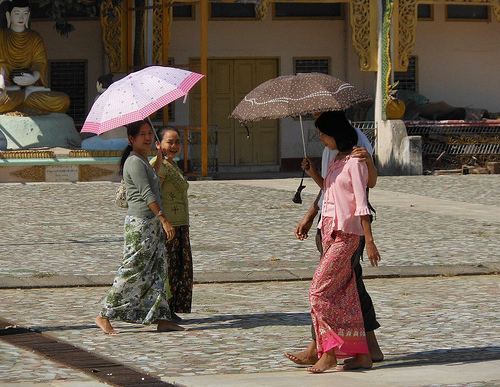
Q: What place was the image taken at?
A: It was taken at the street.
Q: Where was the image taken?
A: It was taken at the street.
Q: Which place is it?
A: It is a street.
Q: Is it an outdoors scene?
A: Yes, it is outdoors.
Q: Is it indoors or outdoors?
A: It is outdoors.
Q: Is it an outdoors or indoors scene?
A: It is outdoors.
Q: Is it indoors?
A: No, it is outdoors.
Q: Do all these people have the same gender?
A: No, they are both male and female.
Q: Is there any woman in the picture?
A: Yes, there is a woman.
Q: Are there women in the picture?
A: Yes, there is a woman.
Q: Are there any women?
A: Yes, there is a woman.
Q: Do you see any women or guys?
A: Yes, there is a woman.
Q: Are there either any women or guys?
A: Yes, there is a woman.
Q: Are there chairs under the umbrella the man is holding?
A: No, there is a woman under the umbrella.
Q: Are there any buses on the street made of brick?
A: No, there is a woman on the street.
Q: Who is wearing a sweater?
A: The woman is wearing a sweater.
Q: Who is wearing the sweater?
A: The woman is wearing a sweater.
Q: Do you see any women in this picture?
A: Yes, there is a woman.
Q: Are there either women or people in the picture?
A: Yes, there is a woman.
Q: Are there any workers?
A: No, there are no workers.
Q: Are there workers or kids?
A: No, there are no workers or kids.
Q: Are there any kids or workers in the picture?
A: No, there are no workers or kids.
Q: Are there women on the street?
A: Yes, there is a woman on the street.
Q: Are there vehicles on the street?
A: No, there is a woman on the street.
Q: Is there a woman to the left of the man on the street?
A: Yes, there is a woman to the left of the man.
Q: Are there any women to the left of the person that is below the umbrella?
A: Yes, there is a woman to the left of the man.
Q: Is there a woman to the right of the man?
A: No, the woman is to the left of the man.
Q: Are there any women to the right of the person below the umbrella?
A: No, the woman is to the left of the man.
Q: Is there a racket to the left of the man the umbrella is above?
A: No, there is a woman to the left of the man.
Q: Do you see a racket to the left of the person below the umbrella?
A: No, there is a woman to the left of the man.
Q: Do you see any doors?
A: Yes, there is a door.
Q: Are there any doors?
A: Yes, there is a door.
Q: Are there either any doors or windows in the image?
A: Yes, there is a door.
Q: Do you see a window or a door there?
A: Yes, there is a door.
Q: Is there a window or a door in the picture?
A: Yes, there is a door.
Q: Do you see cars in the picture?
A: No, there are no cars.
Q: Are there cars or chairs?
A: No, there are no cars or chairs.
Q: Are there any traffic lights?
A: No, there are no traffic lights.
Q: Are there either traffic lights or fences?
A: No, there are no traffic lights or fences.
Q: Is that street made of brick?
A: Yes, the street is made of brick.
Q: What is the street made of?
A: The street is made of brick.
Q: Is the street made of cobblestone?
A: No, the street is made of brick.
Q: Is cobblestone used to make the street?
A: No, the street is made of brick.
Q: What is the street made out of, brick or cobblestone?
A: The street is made of brick.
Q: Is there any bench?
A: No, there are no benches.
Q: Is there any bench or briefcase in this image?
A: No, there are no benches or briefcases.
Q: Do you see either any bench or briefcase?
A: No, there are no benches or briefcases.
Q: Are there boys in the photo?
A: No, there are no boys.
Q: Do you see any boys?
A: No, there are no boys.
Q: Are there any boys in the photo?
A: No, there are no boys.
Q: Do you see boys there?
A: No, there are no boys.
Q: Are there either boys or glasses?
A: No, there are no boys or glasses.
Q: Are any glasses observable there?
A: No, there are no glasses.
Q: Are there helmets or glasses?
A: No, there are no glasses or helmets.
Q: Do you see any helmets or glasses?
A: No, there are no glasses or helmets.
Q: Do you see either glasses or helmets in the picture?
A: No, there are no glasses or helmets.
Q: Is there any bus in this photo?
A: No, there are no buses.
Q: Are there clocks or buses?
A: No, there are no buses or clocks.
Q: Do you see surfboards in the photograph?
A: No, there are no surfboards.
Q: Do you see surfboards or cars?
A: No, there are no surfboards or cars.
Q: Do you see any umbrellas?
A: Yes, there is an umbrella.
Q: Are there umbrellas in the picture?
A: Yes, there is an umbrella.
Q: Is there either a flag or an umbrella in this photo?
A: Yes, there is an umbrella.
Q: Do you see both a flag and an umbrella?
A: No, there is an umbrella but no flags.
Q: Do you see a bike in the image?
A: No, there are no bikes.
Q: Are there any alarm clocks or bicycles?
A: No, there are no bicycles or alarm clocks.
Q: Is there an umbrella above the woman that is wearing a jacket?
A: Yes, there is an umbrella above the woman.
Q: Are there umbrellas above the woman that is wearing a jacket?
A: Yes, there is an umbrella above the woman.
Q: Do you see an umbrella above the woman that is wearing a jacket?
A: Yes, there is an umbrella above the woman.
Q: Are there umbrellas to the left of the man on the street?
A: Yes, there is an umbrella to the left of the man.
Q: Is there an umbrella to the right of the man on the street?
A: No, the umbrella is to the left of the man.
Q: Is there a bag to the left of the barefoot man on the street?
A: No, there is an umbrella to the left of the man.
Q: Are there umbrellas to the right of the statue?
A: Yes, there is an umbrella to the right of the statue.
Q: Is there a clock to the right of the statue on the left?
A: No, there is an umbrella to the right of the statue.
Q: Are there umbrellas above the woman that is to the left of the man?
A: Yes, there is an umbrella above the woman.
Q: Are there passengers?
A: No, there are no passengers.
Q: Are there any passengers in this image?
A: No, there are no passengers.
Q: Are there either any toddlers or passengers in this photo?
A: No, there are no passengers or toddlers.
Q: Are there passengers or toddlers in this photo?
A: No, there are no passengers or toddlers.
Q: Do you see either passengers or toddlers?
A: No, there are no passengers or toddlers.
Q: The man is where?
A: The man is on the street.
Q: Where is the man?
A: The man is on the street.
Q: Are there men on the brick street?
A: Yes, there is a man on the street.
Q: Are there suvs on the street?
A: No, there is a man on the street.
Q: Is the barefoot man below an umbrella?
A: Yes, the man is below an umbrella.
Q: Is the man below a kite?
A: No, the man is below an umbrella.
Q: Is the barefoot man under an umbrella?
A: Yes, the man is under an umbrella.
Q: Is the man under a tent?
A: No, the man is under an umbrella.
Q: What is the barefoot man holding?
A: The man is holding the umbrella.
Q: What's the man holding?
A: The man is holding the umbrella.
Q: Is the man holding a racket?
A: No, the man is holding the umbrella.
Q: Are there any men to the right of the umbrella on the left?
A: Yes, there is a man to the right of the umbrella.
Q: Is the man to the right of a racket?
A: No, the man is to the right of the umbrella.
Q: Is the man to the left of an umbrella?
A: No, the man is to the right of an umbrella.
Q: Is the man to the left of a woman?
A: No, the man is to the right of a woman.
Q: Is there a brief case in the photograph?
A: No, there are no briefcases.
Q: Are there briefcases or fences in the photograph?
A: No, there are no briefcases or fences.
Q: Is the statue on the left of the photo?
A: Yes, the statue is on the left of the image.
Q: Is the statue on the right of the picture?
A: No, the statue is on the left of the image.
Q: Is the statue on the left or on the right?
A: The statue is on the left of the image.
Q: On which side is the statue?
A: The statue is on the left of the image.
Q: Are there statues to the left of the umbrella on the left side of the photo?
A: Yes, there is a statue to the left of the umbrella.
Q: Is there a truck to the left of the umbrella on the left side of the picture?
A: No, there is a statue to the left of the umbrella.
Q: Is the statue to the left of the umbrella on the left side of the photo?
A: Yes, the statue is to the left of the umbrella.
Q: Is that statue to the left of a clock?
A: No, the statue is to the left of the umbrella.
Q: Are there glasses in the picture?
A: No, there are no glasses.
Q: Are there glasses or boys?
A: No, there are no glasses or boys.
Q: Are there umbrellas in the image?
A: Yes, there is an umbrella.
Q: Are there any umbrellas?
A: Yes, there is an umbrella.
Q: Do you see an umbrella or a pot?
A: Yes, there is an umbrella.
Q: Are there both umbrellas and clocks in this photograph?
A: No, there is an umbrella but no clocks.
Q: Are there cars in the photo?
A: No, there are no cars.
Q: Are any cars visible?
A: No, there are no cars.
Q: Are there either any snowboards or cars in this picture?
A: No, there are no cars or snowboards.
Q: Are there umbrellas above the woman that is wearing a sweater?
A: Yes, there is an umbrella above the woman.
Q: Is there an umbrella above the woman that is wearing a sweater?
A: Yes, there is an umbrella above the woman.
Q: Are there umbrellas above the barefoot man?
A: Yes, there is an umbrella above the man.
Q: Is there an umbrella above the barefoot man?
A: Yes, there is an umbrella above the man.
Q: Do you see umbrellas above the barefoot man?
A: Yes, there is an umbrella above the man.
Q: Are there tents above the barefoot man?
A: No, there is an umbrella above the man.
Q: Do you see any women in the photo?
A: Yes, there is a woman.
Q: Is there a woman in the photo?
A: Yes, there is a woman.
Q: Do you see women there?
A: Yes, there is a woman.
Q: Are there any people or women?
A: Yes, there is a woman.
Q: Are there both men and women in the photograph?
A: Yes, there are both a woman and a man.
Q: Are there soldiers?
A: No, there are no soldiers.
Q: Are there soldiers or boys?
A: No, there are no soldiers or boys.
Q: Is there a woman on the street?
A: Yes, there is a woman on the street.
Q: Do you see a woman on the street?
A: Yes, there is a woman on the street.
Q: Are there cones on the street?
A: No, there is a woman on the street.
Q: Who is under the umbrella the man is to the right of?
A: The woman is under the umbrella.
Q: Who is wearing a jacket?
A: The woman is wearing a jacket.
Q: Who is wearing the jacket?
A: The woman is wearing a jacket.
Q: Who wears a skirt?
A: The woman wears a skirt.